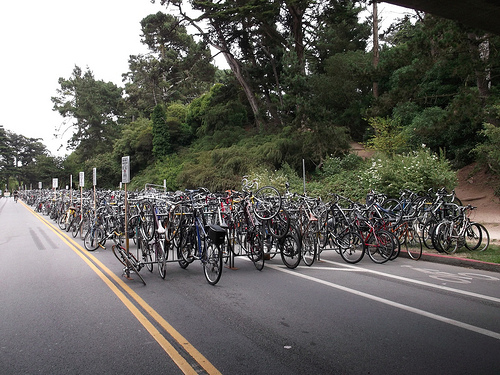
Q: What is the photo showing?
A: It is showing a street.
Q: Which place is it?
A: It is a street.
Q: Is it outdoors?
A: Yes, it is outdoors.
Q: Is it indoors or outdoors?
A: It is outdoors.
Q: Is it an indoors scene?
A: No, it is outdoors.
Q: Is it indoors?
A: No, it is outdoors.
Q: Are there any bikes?
A: Yes, there is a bike.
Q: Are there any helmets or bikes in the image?
A: Yes, there is a bike.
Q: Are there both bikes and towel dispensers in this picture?
A: No, there is a bike but no towel dispensers.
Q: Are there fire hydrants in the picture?
A: No, there are no fire hydrants.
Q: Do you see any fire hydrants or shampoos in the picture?
A: No, there are no fire hydrants or shampoos.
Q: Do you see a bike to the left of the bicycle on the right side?
A: Yes, there is a bike to the left of the bicycle.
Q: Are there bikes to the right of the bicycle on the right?
A: No, the bike is to the left of the bicycle.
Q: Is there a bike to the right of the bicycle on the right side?
A: No, the bike is to the left of the bicycle.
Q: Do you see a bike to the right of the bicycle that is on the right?
A: No, the bike is to the left of the bicycle.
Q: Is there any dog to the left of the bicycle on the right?
A: No, there is a bike to the left of the bicycle.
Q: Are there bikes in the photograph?
A: Yes, there is a bike.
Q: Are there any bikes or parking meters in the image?
A: Yes, there is a bike.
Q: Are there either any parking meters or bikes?
A: Yes, there is a bike.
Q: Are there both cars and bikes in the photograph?
A: No, there is a bike but no cars.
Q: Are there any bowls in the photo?
A: No, there are no bowls.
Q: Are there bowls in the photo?
A: No, there are no bowls.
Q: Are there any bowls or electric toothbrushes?
A: No, there are no bowls or electric toothbrushes.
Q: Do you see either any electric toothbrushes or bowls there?
A: No, there are no bowls or electric toothbrushes.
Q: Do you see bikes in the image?
A: Yes, there is a bike.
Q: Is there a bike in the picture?
A: Yes, there is a bike.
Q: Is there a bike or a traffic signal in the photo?
A: Yes, there is a bike.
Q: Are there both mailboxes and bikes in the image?
A: No, there is a bike but no mailboxes.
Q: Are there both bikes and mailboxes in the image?
A: No, there is a bike but no mailboxes.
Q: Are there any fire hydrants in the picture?
A: No, there are no fire hydrants.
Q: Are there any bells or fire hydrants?
A: No, there are no fire hydrants or bells.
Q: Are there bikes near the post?
A: Yes, there is a bike near the post.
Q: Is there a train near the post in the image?
A: No, there is a bike near the post.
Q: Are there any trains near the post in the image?
A: No, there is a bike near the post.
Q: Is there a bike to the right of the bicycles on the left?
A: Yes, there is a bike to the right of the bicycles.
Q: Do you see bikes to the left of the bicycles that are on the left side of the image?
A: No, the bike is to the right of the bicycles.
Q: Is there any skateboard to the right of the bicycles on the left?
A: No, there is a bike to the right of the bicycles.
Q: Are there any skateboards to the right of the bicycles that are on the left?
A: No, there is a bike to the right of the bicycles.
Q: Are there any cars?
A: No, there are no cars.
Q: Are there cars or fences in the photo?
A: No, there are no cars or fences.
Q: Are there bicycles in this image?
A: Yes, there are bicycles.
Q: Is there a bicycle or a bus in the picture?
A: Yes, there are bicycles.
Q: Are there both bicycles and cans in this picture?
A: No, there are bicycles but no cans.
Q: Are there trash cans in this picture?
A: No, there are no trash cans.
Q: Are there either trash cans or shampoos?
A: No, there are no trash cans or shampoos.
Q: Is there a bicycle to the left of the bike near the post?
A: Yes, there are bicycles to the left of the bike.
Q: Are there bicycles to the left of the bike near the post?
A: Yes, there are bicycles to the left of the bike.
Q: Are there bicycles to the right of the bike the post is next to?
A: No, the bicycles are to the left of the bike.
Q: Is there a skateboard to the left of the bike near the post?
A: No, there are bicycles to the left of the bike.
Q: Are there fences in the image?
A: No, there are no fences.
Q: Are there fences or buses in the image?
A: No, there are no fences or buses.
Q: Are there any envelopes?
A: No, there are no envelopes.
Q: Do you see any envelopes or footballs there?
A: No, there are no envelopes or footballs.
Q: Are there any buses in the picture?
A: No, there are no buses.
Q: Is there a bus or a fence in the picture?
A: No, there are no buses or fences.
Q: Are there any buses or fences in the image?
A: No, there are no buses or fences.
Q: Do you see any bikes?
A: Yes, there is a bike.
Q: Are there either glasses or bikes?
A: Yes, there is a bike.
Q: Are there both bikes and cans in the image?
A: No, there is a bike but no cans.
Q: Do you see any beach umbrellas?
A: No, there are no beach umbrellas.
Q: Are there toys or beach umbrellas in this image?
A: No, there are no beach umbrellas or toys.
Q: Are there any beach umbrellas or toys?
A: No, there are no beach umbrellas or toys.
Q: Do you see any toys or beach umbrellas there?
A: No, there are no beach umbrellas or toys.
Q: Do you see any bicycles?
A: Yes, there is a bicycle.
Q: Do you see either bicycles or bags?
A: Yes, there is a bicycle.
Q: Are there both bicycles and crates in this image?
A: No, there is a bicycle but no crates.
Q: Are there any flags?
A: No, there are no flags.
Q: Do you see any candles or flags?
A: No, there are no flags or candles.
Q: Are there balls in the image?
A: No, there are no balls.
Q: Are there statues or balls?
A: No, there are no balls or statues.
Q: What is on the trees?
A: The leaves are on the trees.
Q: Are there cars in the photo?
A: No, there are no cars.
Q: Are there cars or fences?
A: No, there are no cars or fences.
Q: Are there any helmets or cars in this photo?
A: No, there are no cars or helmets.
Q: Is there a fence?
A: No, there are no fences.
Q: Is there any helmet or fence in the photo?
A: No, there are no fences or helmets.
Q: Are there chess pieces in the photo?
A: No, there are no chess pieces.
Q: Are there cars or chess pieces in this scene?
A: No, there are no chess pieces or cars.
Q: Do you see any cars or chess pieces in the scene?
A: No, there are no chess pieces or cars.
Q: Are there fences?
A: No, there are no fences.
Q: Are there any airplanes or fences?
A: No, there are no fences or airplanes.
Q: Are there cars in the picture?
A: No, there are no cars.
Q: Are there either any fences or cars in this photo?
A: No, there are no cars or fences.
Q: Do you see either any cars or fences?
A: No, there are no cars or fences.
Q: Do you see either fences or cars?
A: No, there are no cars or fences.